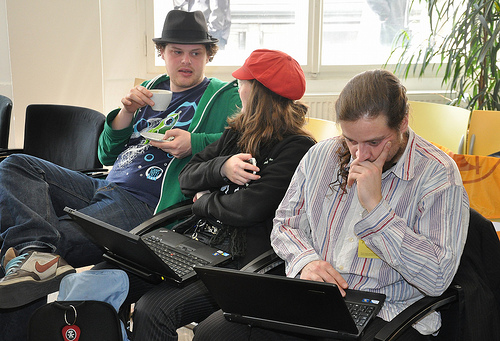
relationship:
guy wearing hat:
[120, 28, 204, 207] [159, 13, 219, 45]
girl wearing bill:
[224, 42, 293, 242] [232, 49, 306, 100]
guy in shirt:
[312, 85, 445, 309] [310, 137, 444, 286]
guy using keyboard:
[312, 85, 445, 309] [271, 282, 382, 312]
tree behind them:
[439, 10, 491, 72] [152, 23, 440, 257]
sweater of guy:
[99, 77, 243, 214] [120, 28, 204, 207]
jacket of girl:
[264, 133, 299, 192] [224, 42, 293, 242]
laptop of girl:
[94, 204, 216, 269] [224, 42, 293, 242]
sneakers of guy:
[3, 253, 76, 299] [120, 28, 204, 207]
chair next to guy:
[19, 98, 102, 157] [120, 28, 204, 207]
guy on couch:
[189, 69, 466, 340] [48, 120, 450, 308]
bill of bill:
[233, 56, 251, 83] [232, 49, 306, 100]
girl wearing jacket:
[74, 49, 314, 341] [171, 127, 314, 269]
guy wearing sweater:
[0, 9, 239, 341] [181, 80, 221, 168]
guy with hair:
[189, 69, 466, 340] [334, 69, 409, 117]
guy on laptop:
[189, 69, 466, 340] [217, 242, 333, 316]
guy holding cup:
[120, 28, 204, 207] [142, 85, 174, 115]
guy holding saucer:
[120, 28, 204, 207] [137, 126, 172, 146]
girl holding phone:
[224, 42, 293, 242] [229, 159, 264, 187]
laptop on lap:
[94, 204, 216, 269] [123, 231, 253, 288]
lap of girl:
[123, 231, 253, 288] [224, 42, 293, 242]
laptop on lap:
[217, 242, 333, 316] [263, 277, 459, 339]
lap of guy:
[263, 277, 459, 339] [312, 85, 445, 309]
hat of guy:
[159, 13, 219, 45] [0, 9, 239, 341]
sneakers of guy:
[3, 253, 76, 299] [189, 69, 466, 340]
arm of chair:
[135, 202, 187, 240] [157, 131, 237, 218]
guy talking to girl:
[0, 9, 239, 341] [74, 49, 314, 341]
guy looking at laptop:
[189, 69, 466, 340] [217, 242, 333, 316]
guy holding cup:
[120, 28, 204, 207] [144, 90, 172, 111]